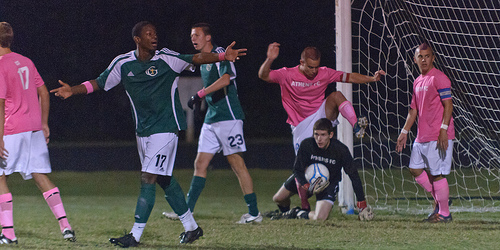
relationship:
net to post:
[348, 1, 499, 213] [332, 1, 357, 212]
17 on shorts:
[151, 150, 168, 170] [407, 137, 454, 174]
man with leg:
[256, 41, 387, 211] [326, 90, 371, 137]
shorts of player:
[133, 132, 178, 177] [98, 18, 205, 248]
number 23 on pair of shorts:
[226, 132, 245, 149] [193, 115, 246, 157]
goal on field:
[332, 0, 499, 211] [8, 135, 494, 247]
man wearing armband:
[50, 20, 251, 248] [81, 80, 94, 94]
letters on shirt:
[309, 151, 338, 168] [292, 135, 365, 206]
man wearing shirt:
[393, 31, 462, 231] [405, 70, 459, 143]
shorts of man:
[4, 133, 51, 173] [50, 20, 248, 248]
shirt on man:
[314, 149, 338, 169] [260, 117, 366, 219]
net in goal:
[348, 1, 499, 213] [332, 0, 499, 211]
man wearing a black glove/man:
[256, 32, 359, 202] [180, 22, 261, 224]